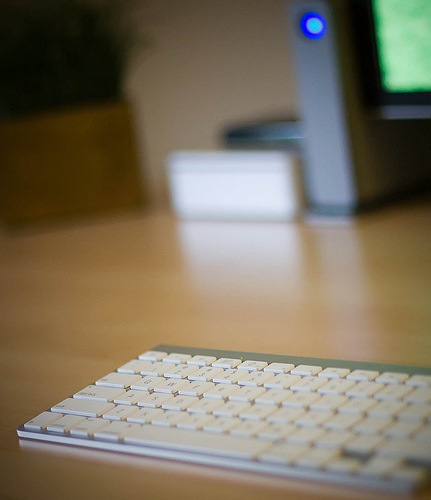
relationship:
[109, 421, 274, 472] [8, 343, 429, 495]
spacebar on keyboard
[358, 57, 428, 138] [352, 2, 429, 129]
computer has monitor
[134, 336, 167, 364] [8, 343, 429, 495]
key on keyboard